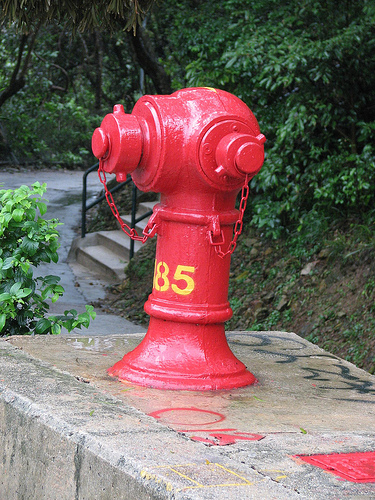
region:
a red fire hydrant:
[79, 67, 333, 470]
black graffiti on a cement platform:
[257, 336, 372, 411]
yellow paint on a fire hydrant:
[137, 253, 210, 307]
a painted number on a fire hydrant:
[152, 255, 213, 303]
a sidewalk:
[40, 226, 115, 323]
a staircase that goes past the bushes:
[80, 166, 179, 274]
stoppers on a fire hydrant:
[89, 103, 266, 261]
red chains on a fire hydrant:
[90, 179, 265, 251]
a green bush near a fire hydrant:
[2, 178, 100, 344]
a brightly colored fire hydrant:
[77, 56, 338, 402]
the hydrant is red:
[46, 62, 273, 402]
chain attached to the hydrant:
[80, 136, 161, 257]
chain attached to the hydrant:
[206, 149, 266, 300]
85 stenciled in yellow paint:
[150, 256, 204, 303]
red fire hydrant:
[88, 83, 269, 395]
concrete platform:
[0, 326, 373, 498]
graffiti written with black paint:
[213, 324, 374, 419]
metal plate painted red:
[292, 443, 373, 486]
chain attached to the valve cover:
[200, 152, 257, 261]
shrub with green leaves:
[3, 172, 94, 345]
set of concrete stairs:
[76, 196, 151, 301]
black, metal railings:
[64, 142, 158, 265]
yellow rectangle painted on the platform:
[144, 457, 255, 496]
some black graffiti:
[229, 320, 366, 409]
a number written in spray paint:
[147, 255, 200, 303]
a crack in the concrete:
[96, 393, 277, 485]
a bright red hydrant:
[90, 85, 266, 393]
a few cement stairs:
[73, 200, 159, 270]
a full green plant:
[0, 185, 98, 342]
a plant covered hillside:
[237, 199, 368, 365]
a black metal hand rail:
[79, 159, 139, 229]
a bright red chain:
[207, 175, 252, 258]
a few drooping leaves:
[0, 3, 155, 39]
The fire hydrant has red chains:
[94, 156, 249, 260]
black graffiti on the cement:
[226, 328, 373, 403]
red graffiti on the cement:
[145, 405, 267, 450]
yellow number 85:
[152, 257, 195, 296]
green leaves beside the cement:
[1, 181, 97, 335]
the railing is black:
[80, 161, 156, 263]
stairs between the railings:
[70, 165, 157, 285]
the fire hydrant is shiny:
[88, 84, 268, 389]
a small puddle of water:
[45, 183, 98, 219]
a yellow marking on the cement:
[138, 458, 250, 498]